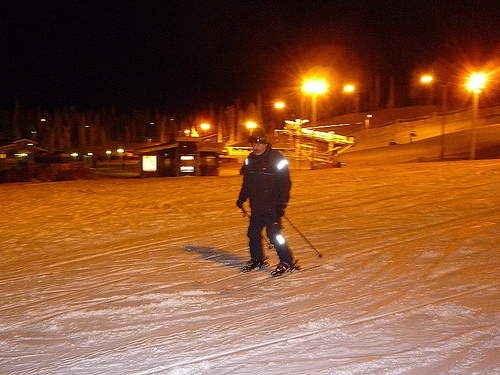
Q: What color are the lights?
A: Yellow.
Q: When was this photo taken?
A: During the night.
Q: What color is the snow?
A: White.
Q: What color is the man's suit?
A: Black.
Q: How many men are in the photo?
A: One.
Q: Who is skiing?
A: The man.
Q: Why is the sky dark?
A: It is night time.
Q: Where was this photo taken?
A: On a ski slope.